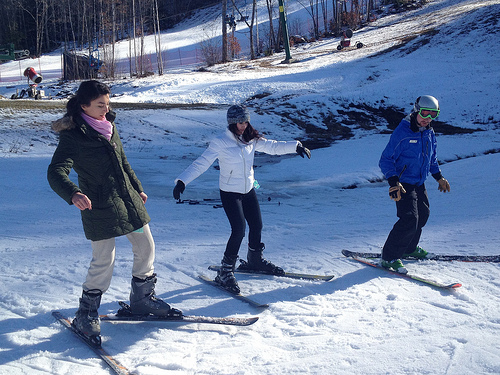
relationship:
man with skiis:
[363, 63, 442, 228] [358, 230, 500, 318]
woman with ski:
[15, 16, 149, 277] [113, 272, 345, 317]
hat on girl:
[218, 98, 252, 139] [209, 87, 307, 255]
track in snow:
[254, 281, 330, 340] [290, 164, 340, 283]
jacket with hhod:
[384, 116, 438, 203] [394, 107, 423, 122]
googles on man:
[392, 84, 458, 134] [363, 63, 442, 228]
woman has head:
[15, 16, 149, 277] [62, 69, 118, 113]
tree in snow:
[29, 8, 238, 92] [290, 164, 340, 283]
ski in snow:
[113, 272, 345, 317] [290, 164, 340, 283]